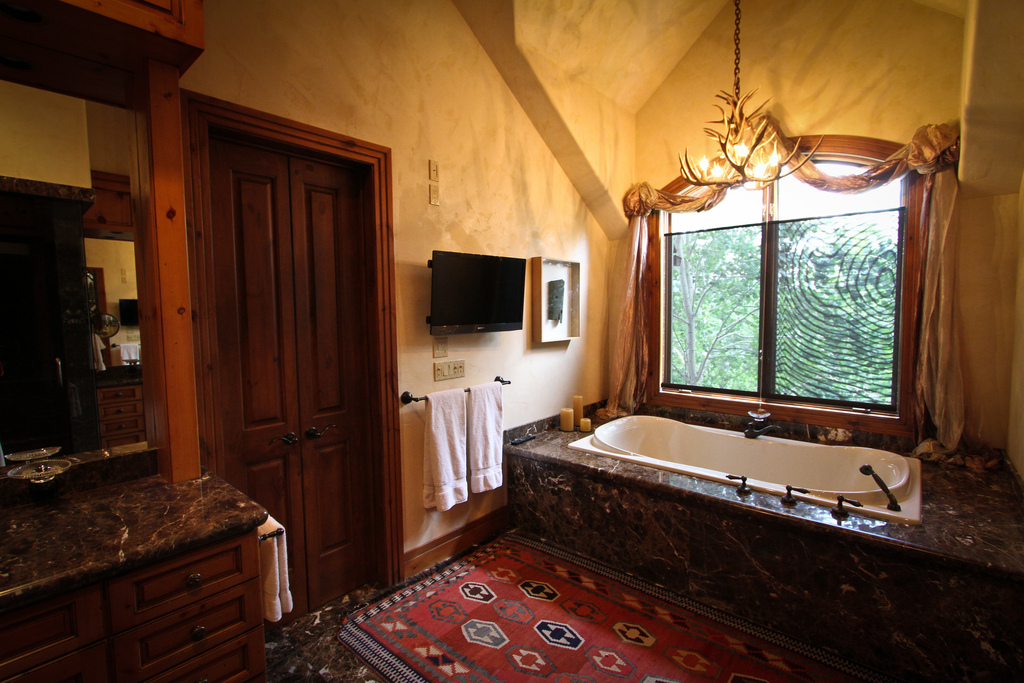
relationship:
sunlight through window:
[662, 163, 905, 406] [652, 154, 908, 421]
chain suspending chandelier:
[730, 5, 743, 95] [677, 93, 818, 185]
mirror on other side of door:
[31, 83, 188, 360] [167, 84, 461, 607]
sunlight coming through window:
[662, 163, 905, 406] [531, 246, 896, 512]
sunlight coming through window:
[625, 211, 914, 399] [625, 211, 914, 399]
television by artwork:
[405, 242, 539, 347] [571, 242, 629, 347]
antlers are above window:
[650, 100, 853, 236] [650, 100, 888, 442]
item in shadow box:
[536, 273, 607, 332] [536, 273, 607, 332]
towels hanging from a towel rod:
[419, 377, 509, 515] [393, 368, 530, 411]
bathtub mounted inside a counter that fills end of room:
[573, 435, 929, 518] [45, 262, 1022, 569]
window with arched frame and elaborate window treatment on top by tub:
[637, 130, 933, 445] [540, 500, 938, 557]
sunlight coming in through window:
[662, 163, 905, 406] [651, 189, 987, 450]